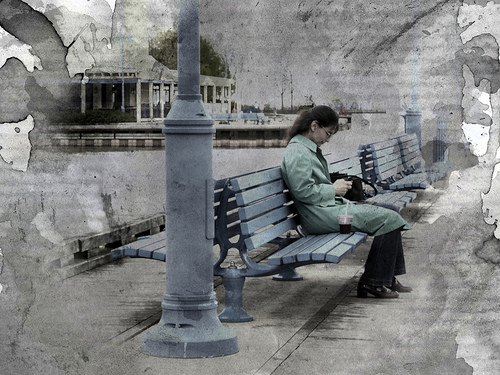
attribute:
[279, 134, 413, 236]
coat — green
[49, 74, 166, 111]
pillars — exterior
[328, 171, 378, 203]
bag — black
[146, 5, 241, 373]
pole — gray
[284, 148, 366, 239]
coat — long, green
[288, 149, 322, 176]
jacket part — green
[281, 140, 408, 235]
green coat — pale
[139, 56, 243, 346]
pole — metal, light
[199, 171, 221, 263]
panel — electrical access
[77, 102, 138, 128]
bush — green, small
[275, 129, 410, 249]
coat — rain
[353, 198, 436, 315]
pants — black